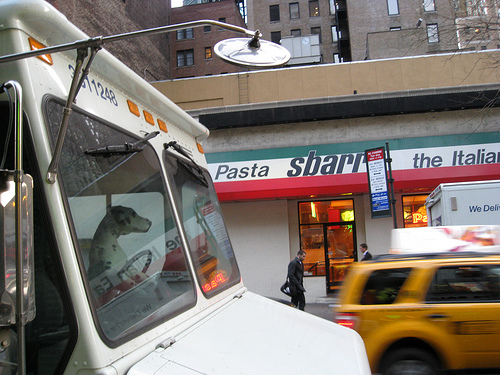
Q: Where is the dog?
A: The van.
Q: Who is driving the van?
A: A dog.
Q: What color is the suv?
A: Yellow.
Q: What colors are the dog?
A: Black and white.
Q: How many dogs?
A: One.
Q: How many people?
A: Two.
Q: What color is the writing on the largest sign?
A: Black.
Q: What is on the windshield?
A: Wipers.